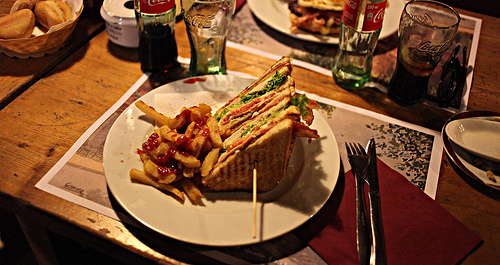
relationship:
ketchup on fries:
[137, 110, 215, 177] [126, 97, 222, 208]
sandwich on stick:
[198, 54, 321, 194] [243, 170, 263, 238]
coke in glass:
[394, 61, 426, 99] [398, 9, 450, 74]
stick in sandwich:
[243, 167, 261, 239] [200, 93, 315, 195]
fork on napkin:
[342, 140, 372, 262] [318, 157, 485, 263]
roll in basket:
[34, 0, 84, 32] [4, 0, 85, 59]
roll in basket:
[0, 8, 34, 41] [4, 0, 85, 59]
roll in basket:
[5, 0, 36, 15] [4, 0, 85, 59]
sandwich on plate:
[198, 54, 321, 200] [279, 176, 333, 228]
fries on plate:
[129, 100, 220, 202] [279, 176, 333, 228]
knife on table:
[367, 137, 388, 265] [100, 68, 342, 251]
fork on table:
[342, 140, 372, 262] [100, 68, 342, 251]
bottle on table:
[135, 1, 180, 74] [22, 60, 184, 237]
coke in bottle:
[135, 23, 178, 76] [135, 1, 180, 74]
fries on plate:
[129, 101, 221, 205] [102, 74, 342, 247]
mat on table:
[36, 50, 443, 265] [2, 1, 499, 263]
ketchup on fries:
[137, 110, 215, 177] [129, 101, 221, 205]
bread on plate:
[202, 119, 294, 192] [102, 74, 342, 247]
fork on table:
[342, 140, 372, 262] [2, 1, 499, 263]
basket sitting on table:
[4, 0, 85, 59] [2, 1, 499, 263]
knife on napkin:
[367, 137, 388, 265] [298, 156, 484, 260]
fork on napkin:
[342, 140, 372, 262] [298, 156, 484, 260]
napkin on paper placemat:
[376, 172, 438, 260] [382, 112, 447, 184]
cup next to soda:
[386, 0, 458, 110] [340, 2, 389, 133]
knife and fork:
[367, 137, 386, 262] [344, 139, 369, 259]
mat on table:
[31, 50, 444, 262] [2, 1, 499, 263]